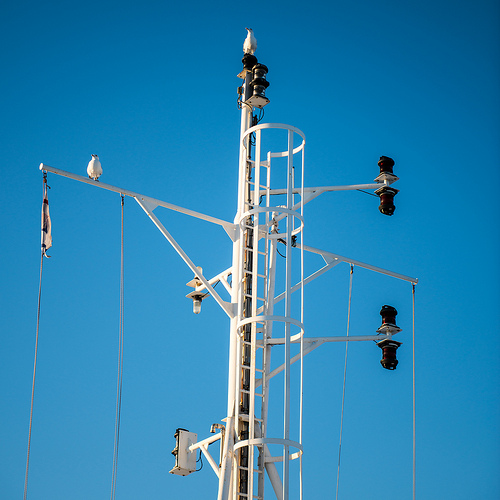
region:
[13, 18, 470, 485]
this is a tower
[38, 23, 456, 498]
the tower is white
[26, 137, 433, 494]
lines attached to tower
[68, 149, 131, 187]
this is a bird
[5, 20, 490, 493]
bird on top of tower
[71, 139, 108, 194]
the bird is white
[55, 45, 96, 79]
white clouds in blue sky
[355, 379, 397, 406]
white clouds in blue sky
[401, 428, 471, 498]
white clouds in blue sky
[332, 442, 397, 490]
white clouds in blue sky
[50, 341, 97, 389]
white clouds in blue sky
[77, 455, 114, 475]
white clouds in blue sky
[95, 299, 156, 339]
white clouds in blue sky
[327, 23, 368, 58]
white clouds in blue sky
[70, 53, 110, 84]
white clouds in blue sky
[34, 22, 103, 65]
white clouds in blue sky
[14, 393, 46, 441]
white clouds in blue sky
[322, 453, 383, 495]
white clouds in blue sky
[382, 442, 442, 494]
white clouds in blue sky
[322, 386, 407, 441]
white clouds in blue sky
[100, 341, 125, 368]
white clouds in blue sky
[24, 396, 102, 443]
white clouds in blue sky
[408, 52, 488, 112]
white clouds in blue sky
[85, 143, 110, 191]
white bird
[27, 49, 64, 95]
blue sky with no clouds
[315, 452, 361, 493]
blue sky with no clouds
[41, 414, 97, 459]
blue sky with no clouds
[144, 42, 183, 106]
blue sky with no clouds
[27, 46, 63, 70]
blue sky with no clouds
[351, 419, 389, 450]
white clouds in blue sky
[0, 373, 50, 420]
white clouds in blue sky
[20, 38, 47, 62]
white clouds in blue sky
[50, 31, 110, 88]
white clouds in blue sky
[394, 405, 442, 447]
white clouds in blue sky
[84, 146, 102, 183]
a seagull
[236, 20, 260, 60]
a seagull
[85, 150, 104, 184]
white bird sitting on a metal bar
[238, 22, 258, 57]
white bird sitting on top of a utility pole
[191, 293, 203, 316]
clear glass light bulb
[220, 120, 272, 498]
tall white metal ladder against a pole